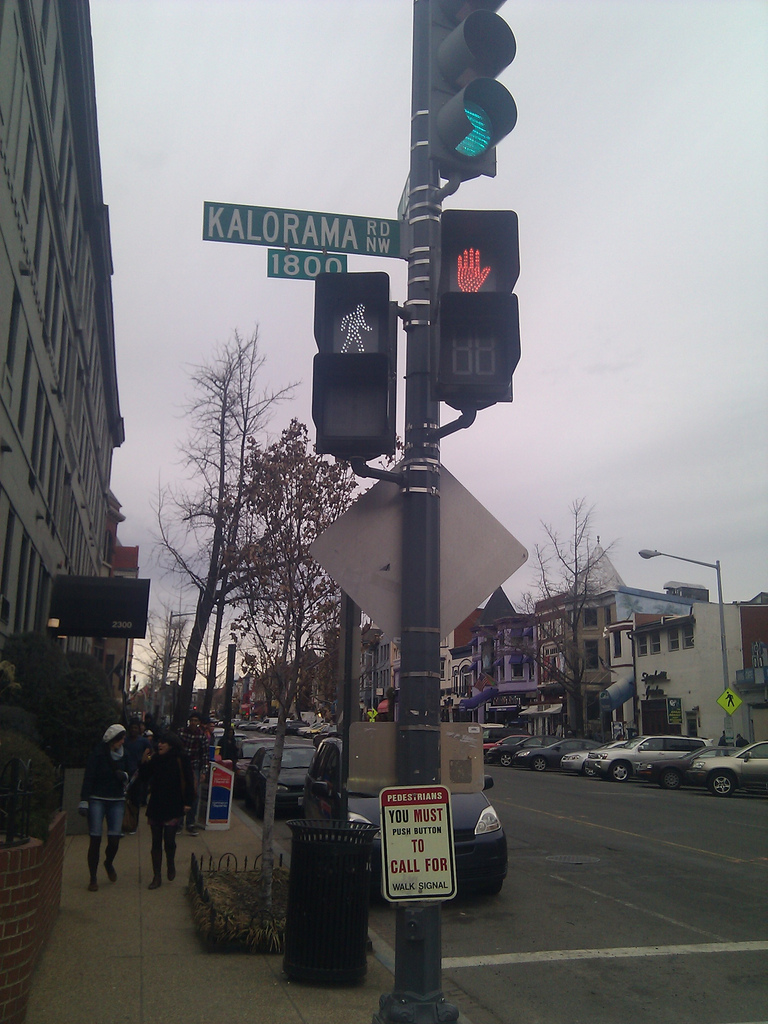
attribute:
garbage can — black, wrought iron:
[275, 812, 381, 995]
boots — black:
[87, 837, 118, 888]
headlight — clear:
[348, 808, 378, 840]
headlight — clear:
[465, 803, 499, 836]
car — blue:
[304, 730, 508, 907]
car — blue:
[517, 735, 603, 771]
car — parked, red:
[454, 698, 578, 798]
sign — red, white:
[372, 776, 461, 917]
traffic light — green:
[430, 22, 524, 170]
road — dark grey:
[451, 774, 756, 1009]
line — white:
[430, 927, 763, 999]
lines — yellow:
[632, 777, 729, 894]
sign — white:
[374, 786, 460, 914]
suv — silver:
[591, 710, 698, 770]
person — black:
[725, 689, 738, 709]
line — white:
[445, 934, 767, 954]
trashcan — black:
[301, 807, 380, 984]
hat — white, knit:
[104, 720, 129, 733]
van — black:
[308, 747, 510, 906]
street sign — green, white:
[198, 203, 401, 263]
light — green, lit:
[471, 111, 494, 137]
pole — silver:
[658, 543, 733, 744]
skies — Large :
[72, 4, 764, 702]